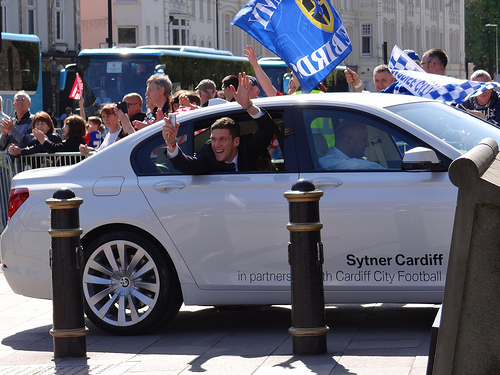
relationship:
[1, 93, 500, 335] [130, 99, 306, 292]
sedan has doors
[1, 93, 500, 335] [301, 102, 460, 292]
sedan has doors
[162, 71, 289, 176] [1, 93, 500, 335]
man inside sedan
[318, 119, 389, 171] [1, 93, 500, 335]
man inside sedan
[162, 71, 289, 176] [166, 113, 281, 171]
man wearing jacket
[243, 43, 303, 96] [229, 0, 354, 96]
person holding flag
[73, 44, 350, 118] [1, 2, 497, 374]
bus in city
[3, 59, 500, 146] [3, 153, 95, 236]
crowd behind fence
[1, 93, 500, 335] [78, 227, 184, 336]
sedan has tire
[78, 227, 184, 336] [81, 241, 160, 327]
tire has rims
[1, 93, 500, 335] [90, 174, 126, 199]
sedan has gas tank door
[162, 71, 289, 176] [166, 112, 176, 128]
man holding phone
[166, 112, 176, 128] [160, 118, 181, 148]
phone in hand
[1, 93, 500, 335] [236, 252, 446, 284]
sedan has writing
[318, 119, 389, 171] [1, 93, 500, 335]
man in sedan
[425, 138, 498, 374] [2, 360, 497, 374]
gray object on sidewalk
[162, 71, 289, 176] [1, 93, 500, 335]
man in sedan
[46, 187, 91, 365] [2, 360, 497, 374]
pole on sidewalk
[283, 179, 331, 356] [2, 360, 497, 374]
pole on sidewalk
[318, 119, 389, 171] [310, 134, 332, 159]
man in front seat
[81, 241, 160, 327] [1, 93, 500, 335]
rims on sedan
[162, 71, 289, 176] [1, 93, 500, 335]
man hanging out of sedan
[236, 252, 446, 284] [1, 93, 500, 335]
writing on sedan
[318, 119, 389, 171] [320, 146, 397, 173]
man wearing shirt